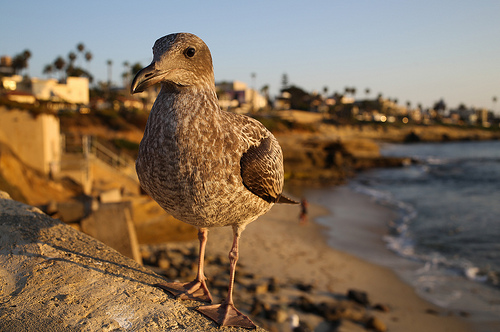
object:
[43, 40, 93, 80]
palm trees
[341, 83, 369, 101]
palm trees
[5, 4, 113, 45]
sky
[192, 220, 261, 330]
legs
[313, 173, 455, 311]
shore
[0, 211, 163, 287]
black shadow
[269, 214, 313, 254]
sand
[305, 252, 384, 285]
sand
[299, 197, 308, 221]
person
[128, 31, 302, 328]
bird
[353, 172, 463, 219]
waves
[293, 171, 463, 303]
beach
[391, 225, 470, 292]
wave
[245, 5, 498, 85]
sky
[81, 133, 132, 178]
stairs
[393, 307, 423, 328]
sand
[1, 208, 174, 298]
shadow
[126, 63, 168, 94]
beak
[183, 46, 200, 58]
eye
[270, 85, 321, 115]
buildings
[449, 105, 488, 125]
buildings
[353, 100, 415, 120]
buildings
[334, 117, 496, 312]
sea shore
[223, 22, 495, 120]
background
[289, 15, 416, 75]
clouds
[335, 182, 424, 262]
shoreline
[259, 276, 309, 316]
rocks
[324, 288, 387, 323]
debris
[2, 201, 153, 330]
rock